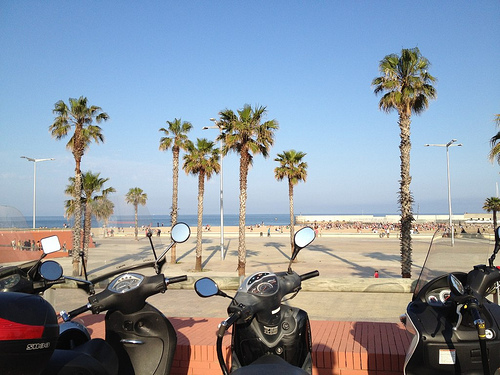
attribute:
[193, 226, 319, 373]
motorbike — black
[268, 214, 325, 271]
mirror — sideview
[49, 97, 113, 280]
palm tree — grouped, four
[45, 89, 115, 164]
leaves — green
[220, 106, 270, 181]
fronds — palm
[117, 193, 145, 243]
tree — palm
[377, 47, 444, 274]
tree — grouped, palm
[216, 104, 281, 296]
tree — green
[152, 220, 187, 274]
mirror — attached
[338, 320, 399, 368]
brick — short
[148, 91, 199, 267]
leaves — green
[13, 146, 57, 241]
lamp — street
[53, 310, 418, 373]
brick wall — red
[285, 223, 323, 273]
mirror — attached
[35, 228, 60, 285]
mirrors — attached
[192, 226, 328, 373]
scooter — parked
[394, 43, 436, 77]
leaves — green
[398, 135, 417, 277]
trunk — palm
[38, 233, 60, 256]
mirror — sideview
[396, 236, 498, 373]
motorbike — black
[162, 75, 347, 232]
tree — tall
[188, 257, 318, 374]
motorbike — black